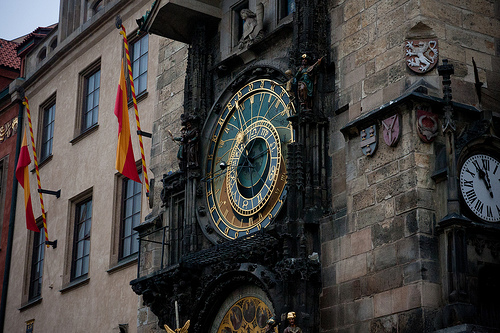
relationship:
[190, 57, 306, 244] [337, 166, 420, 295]
clock near wall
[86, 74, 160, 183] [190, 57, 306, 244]
flag near clock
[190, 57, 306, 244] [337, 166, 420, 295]
clock on wall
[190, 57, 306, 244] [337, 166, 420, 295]
clock by wall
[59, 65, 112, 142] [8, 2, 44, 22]
window near sky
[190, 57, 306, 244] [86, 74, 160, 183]
clock by flag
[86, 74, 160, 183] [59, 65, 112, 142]
flag near window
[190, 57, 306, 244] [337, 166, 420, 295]
clock in wall